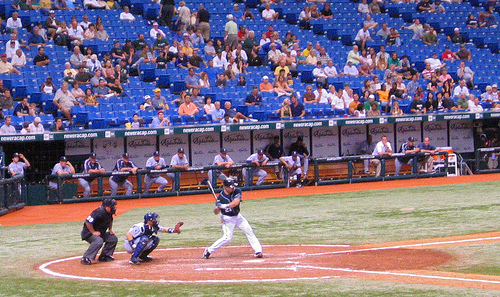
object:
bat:
[204, 179, 220, 204]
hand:
[212, 206, 222, 215]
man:
[424, 52, 446, 70]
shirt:
[455, 65, 474, 79]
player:
[202, 177, 265, 259]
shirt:
[213, 187, 243, 216]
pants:
[207, 213, 263, 255]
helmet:
[142, 211, 160, 225]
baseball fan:
[243, 86, 264, 106]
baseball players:
[107, 152, 138, 197]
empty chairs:
[99, 104, 113, 113]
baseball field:
[0, 172, 500, 297]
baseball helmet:
[223, 176, 239, 188]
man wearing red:
[238, 25, 248, 38]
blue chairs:
[91, 118, 106, 129]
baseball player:
[122, 210, 185, 265]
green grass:
[0, 181, 499, 296]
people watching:
[176, 93, 200, 115]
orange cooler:
[434, 147, 454, 161]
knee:
[223, 236, 235, 243]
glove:
[173, 221, 185, 235]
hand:
[91, 229, 101, 237]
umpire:
[80, 197, 120, 267]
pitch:
[306, 249, 453, 273]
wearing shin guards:
[123, 212, 187, 266]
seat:
[156, 74, 171, 86]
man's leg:
[236, 221, 265, 252]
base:
[240, 258, 267, 264]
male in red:
[440, 51, 453, 61]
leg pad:
[140, 234, 160, 258]